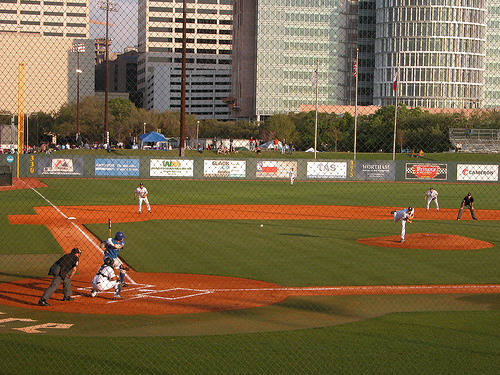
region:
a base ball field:
[2, 174, 487, 331]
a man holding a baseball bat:
[92, 215, 133, 255]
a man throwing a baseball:
[397, 207, 416, 239]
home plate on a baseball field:
[121, 274, 163, 311]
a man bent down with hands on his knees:
[449, 186, 478, 236]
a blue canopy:
[141, 132, 168, 147]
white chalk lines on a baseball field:
[126, 283, 298, 308]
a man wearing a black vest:
[27, 242, 82, 322]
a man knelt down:
[93, 257, 119, 302]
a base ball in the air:
[238, 211, 285, 249]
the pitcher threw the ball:
[370, 198, 417, 258]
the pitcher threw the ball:
[236, 190, 464, 295]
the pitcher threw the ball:
[348, 183, 418, 275]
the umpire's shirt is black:
[28, 235, 101, 332]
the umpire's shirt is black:
[46, 249, 84, 280]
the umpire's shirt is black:
[56, 248, 114, 279]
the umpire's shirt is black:
[40, 242, 97, 273]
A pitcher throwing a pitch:
[384, 205, 422, 243]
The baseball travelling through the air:
[258, 222, 267, 230]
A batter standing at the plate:
[99, 219, 129, 287]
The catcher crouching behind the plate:
[90, 256, 124, 301]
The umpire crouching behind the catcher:
[31, 244, 83, 306]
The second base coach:
[458, 191, 477, 223]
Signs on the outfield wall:
[36, 150, 497, 191]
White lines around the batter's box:
[66, 277, 220, 310]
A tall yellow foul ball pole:
[9, 57, 30, 178]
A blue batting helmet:
[112, 229, 126, 244]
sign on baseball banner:
[31, 151, 88, 183]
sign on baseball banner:
[93, 159, 142, 176]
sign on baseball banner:
[150, 159, 194, 177]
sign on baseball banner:
[201, 159, 244, 177]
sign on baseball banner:
[255, 162, 297, 179]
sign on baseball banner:
[303, 163, 350, 181]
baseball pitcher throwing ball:
[388, 202, 417, 244]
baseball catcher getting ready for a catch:
[88, 254, 123, 299]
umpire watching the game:
[36, 244, 82, 310]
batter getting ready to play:
[102, 219, 137, 287]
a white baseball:
[257, 221, 268, 227]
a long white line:
[214, 280, 497, 291]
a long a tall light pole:
[67, 35, 92, 136]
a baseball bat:
[104, 213, 114, 241]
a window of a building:
[285, 29, 292, 38]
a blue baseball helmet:
[114, 228, 125, 239]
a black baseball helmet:
[71, 242, 81, 253]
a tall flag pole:
[345, 45, 364, 157]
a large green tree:
[259, 110, 302, 145]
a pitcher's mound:
[355, 228, 496, 252]